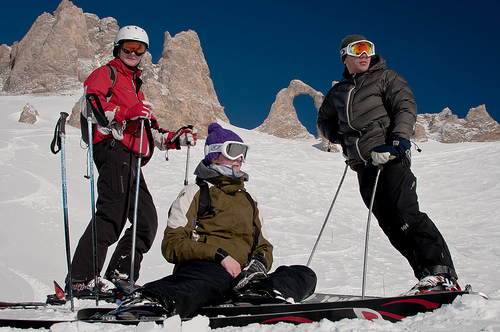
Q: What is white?
A: Snow.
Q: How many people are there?
A: Three.